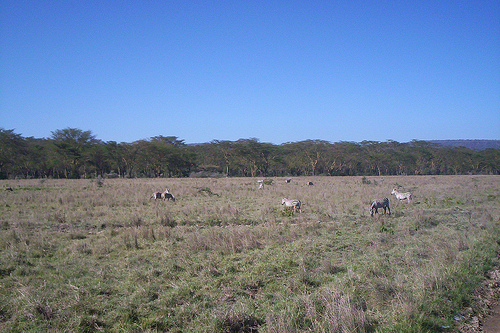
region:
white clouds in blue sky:
[24, 15, 64, 55]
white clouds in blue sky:
[347, 30, 397, 75]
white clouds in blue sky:
[256, 37, 304, 94]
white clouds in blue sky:
[166, 52, 230, 90]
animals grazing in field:
[243, 178, 424, 227]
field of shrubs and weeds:
[2, 178, 498, 332]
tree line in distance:
[2, 128, 499, 177]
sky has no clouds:
[2, 1, 499, 138]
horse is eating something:
[370, 198, 390, 215]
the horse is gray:
[367, 199, 391, 215]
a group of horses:
[152, 178, 410, 216]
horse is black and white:
[152, 191, 174, 203]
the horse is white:
[389, 186, 412, 201]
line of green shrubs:
[412, 219, 497, 330]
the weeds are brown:
[266, 288, 368, 332]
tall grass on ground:
[136, 285, 176, 329]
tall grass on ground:
[195, 283, 240, 310]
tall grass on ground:
[210, 208, 249, 264]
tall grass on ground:
[170, 213, 202, 258]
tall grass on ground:
[119, 221, 179, 272]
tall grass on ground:
[78, 221, 114, 249]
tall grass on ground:
[55, 220, 87, 265]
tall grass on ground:
[404, 248, 445, 288]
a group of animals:
[129, 172, 419, 224]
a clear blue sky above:
[4, 0, 496, 118]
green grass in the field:
[135, 235, 245, 300]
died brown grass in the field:
[190, 220, 266, 260]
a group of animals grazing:
[115, 170, 430, 245]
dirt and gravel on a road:
[450, 270, 495, 327]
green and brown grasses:
[116, 220, 347, 296]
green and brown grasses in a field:
[2, 213, 499, 332]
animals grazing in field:
[140, 178, 197, 215]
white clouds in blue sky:
[382, 86, 405, 106]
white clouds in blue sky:
[221, 30, 273, 74]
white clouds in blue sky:
[151, 13, 217, 66]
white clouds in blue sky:
[191, 95, 233, 124]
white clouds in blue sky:
[118, 24, 159, 66]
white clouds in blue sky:
[69, 33, 124, 62]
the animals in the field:
[154, 162, 414, 232]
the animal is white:
[390, 187, 420, 208]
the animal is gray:
[360, 190, 395, 224]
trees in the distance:
[85, 135, 446, 177]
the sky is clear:
[9, 15, 489, 135]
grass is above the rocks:
[430, 269, 494, 327]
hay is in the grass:
[290, 244, 435, 326]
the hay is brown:
[170, 226, 328, 265]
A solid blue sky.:
[0, 1, 499, 140]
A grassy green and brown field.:
[1, 176, 496, 330]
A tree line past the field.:
[1, 127, 499, 177]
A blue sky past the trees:
[1, 0, 498, 138]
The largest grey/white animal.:
[390, 187, 413, 204]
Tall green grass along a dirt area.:
[389, 227, 498, 332]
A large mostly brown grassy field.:
[1, 174, 498, 332]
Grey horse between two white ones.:
[366, 198, 390, 215]